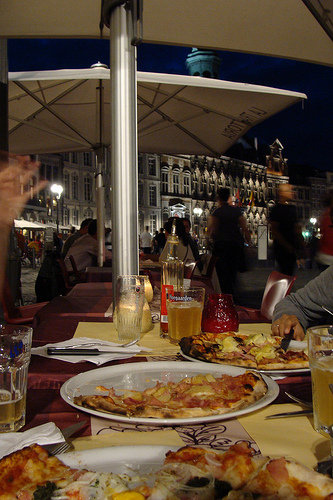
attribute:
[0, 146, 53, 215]
hand — here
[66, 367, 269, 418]
pizza — delicious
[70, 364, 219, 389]
plate — here, white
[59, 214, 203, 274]
people — sitting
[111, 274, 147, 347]
glass — empty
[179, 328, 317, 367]
almost whole pizza — here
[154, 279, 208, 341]
beer — here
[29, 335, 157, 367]
napkin — here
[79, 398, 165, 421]
crust — thin, white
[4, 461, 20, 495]
tomato sauce — red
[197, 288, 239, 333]
candle holder — red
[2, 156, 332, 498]
restaurant — here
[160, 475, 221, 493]
onions — yellow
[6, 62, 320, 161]
umbrella — here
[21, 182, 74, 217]
streetlight — lit